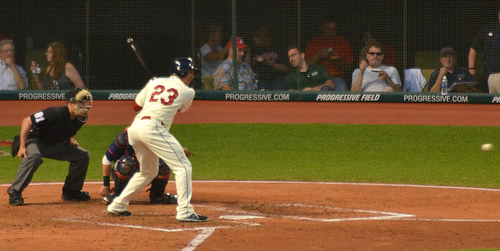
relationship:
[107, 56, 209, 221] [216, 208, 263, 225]
batter at homeplate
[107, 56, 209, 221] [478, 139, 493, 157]
batter looking at ball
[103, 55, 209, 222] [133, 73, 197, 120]
man wearing shirt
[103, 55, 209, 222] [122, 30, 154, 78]
man holds bat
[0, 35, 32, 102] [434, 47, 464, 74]
man touches face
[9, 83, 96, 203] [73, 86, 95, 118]
man has mask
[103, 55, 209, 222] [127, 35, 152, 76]
man has bat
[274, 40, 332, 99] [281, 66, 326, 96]
man wears shirt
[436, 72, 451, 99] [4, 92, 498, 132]
water bottle behind fence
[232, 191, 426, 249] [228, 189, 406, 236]
lines indicating batter's box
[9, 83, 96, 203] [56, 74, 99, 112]
man possesses face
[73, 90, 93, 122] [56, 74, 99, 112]
mask on face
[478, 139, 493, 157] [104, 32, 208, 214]
ball moving towards batter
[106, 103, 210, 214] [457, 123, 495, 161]
catcher waiting on baseball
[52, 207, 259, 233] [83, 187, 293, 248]
chalk outline of box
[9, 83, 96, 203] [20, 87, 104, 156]
man wearing shirt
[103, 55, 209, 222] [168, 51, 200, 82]
man wearing helmet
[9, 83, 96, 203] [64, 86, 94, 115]
man wearing safety mask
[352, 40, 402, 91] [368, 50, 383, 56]
man wearing sunglasses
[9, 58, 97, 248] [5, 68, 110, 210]
man wearing uniform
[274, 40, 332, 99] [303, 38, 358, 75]
man wearing shirt